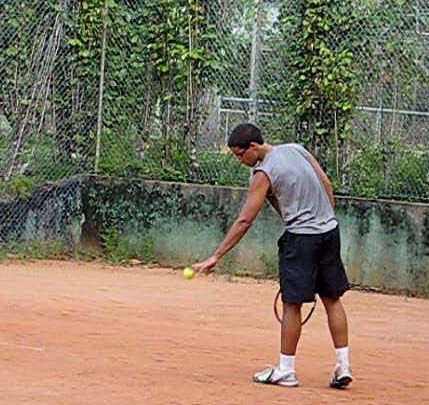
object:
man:
[187, 122, 353, 389]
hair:
[227, 122, 264, 152]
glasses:
[236, 146, 249, 158]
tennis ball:
[183, 267, 195, 280]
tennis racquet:
[274, 287, 317, 327]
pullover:
[252, 143, 339, 234]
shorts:
[276, 225, 351, 304]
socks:
[278, 346, 352, 374]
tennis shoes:
[252, 363, 354, 389]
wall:
[1, 172, 429, 301]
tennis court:
[1, 256, 427, 404]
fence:
[2, 2, 429, 248]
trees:
[261, 2, 428, 206]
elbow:
[235, 218, 252, 232]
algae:
[338, 197, 428, 300]